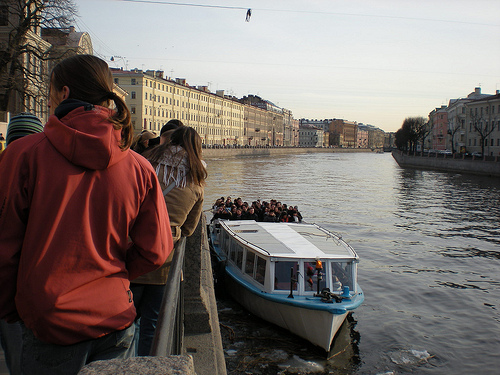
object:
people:
[140, 125, 199, 286]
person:
[5, 53, 164, 366]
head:
[43, 52, 121, 146]